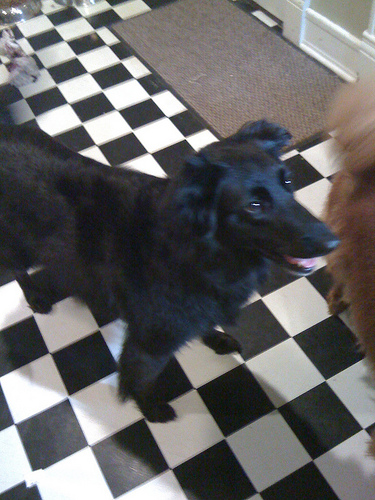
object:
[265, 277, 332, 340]
white square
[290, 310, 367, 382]
black square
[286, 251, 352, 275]
tongue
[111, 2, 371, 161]
doormat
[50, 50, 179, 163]
tiles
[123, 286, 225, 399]
legs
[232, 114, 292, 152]
ears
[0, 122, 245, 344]
body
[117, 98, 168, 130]
square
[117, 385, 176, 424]
paw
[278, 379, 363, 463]
square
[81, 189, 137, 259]
fur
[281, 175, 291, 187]
dogeye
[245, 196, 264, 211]
dogeye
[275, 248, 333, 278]
mouth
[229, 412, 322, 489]
white square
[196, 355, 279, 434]
black square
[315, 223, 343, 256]
nose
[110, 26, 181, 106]
edges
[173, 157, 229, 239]
ear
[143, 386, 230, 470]
square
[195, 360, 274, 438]
square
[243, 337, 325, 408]
square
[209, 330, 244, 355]
paw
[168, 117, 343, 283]
head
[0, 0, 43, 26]
dish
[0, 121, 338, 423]
black dog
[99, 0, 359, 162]
floor